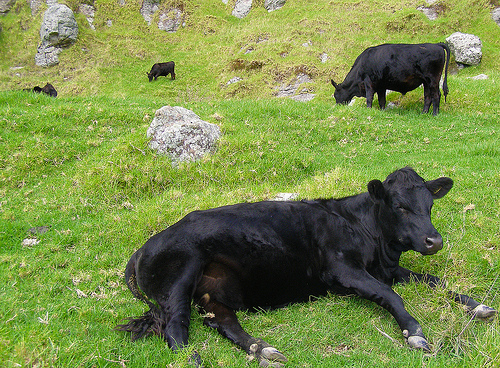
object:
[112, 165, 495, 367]
cows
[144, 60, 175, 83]
cow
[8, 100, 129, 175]
grass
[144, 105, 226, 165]
rock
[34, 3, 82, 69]
rock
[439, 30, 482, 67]
rock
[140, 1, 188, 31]
grey rock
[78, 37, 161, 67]
grass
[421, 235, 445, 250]
nose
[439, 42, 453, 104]
tail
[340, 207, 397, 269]
wrinkles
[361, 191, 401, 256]
neck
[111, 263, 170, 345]
tail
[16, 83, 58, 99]
cows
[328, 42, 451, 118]
cows